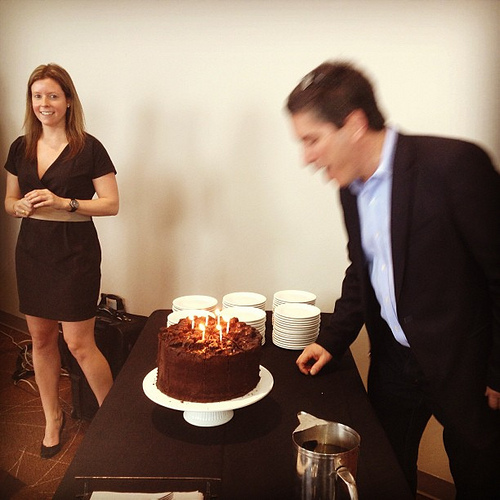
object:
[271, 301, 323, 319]
plate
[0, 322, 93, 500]
floor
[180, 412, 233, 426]
stand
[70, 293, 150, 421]
suitcase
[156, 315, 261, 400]
cake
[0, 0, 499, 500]
diner room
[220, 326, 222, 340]
candles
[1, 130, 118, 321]
dress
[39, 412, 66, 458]
pumps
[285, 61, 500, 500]
man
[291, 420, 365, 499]
silver pitcher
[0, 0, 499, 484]
white wall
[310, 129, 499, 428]
suit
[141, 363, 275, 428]
dish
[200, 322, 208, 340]
candles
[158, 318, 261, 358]
sprinkles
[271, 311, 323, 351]
stacks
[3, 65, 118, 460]
woman